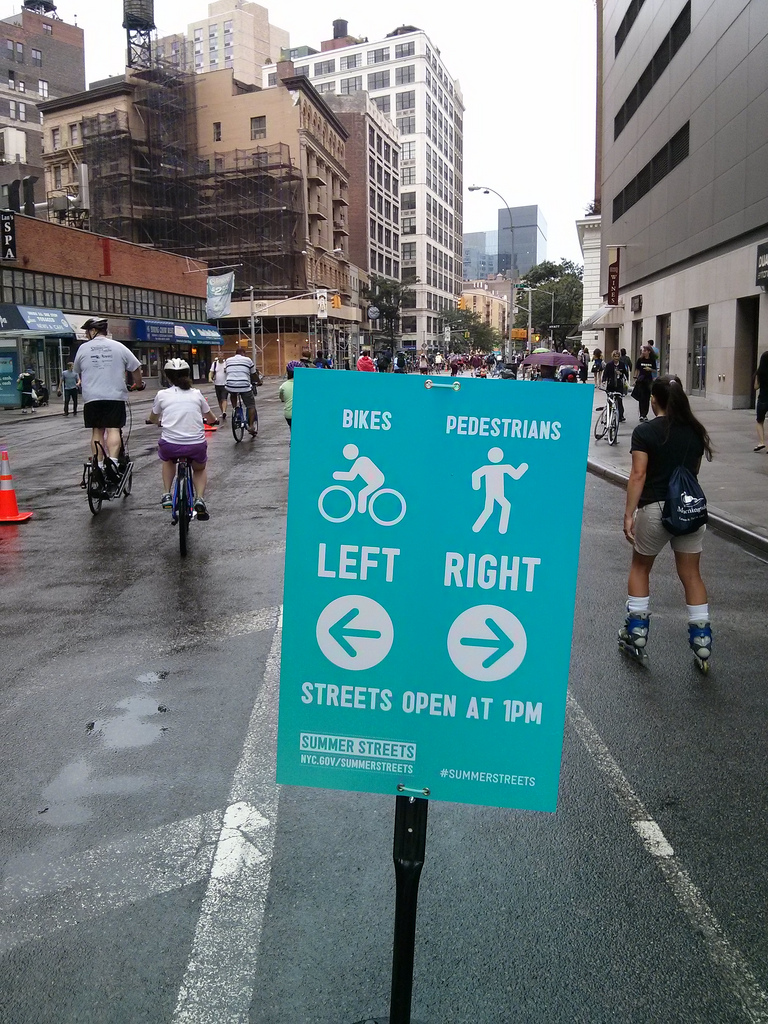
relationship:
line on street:
[576, 681, 763, 1017] [3, 386, 748, 1015]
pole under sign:
[387, 790, 433, 1017] [283, 360, 598, 824]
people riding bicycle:
[52, 316, 265, 457] [141, 409, 225, 576]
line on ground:
[561, 681, 761, 1017] [2, 379, 761, 1010]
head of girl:
[648, 373, 685, 416] [617, 368, 721, 676]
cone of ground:
[2, 446, 29, 518] [2, 379, 761, 1010]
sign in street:
[270, 365, 605, 845] [3, 386, 748, 1015]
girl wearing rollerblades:
[606, 332, 736, 699] [612, 598, 719, 680]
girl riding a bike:
[147, 309, 222, 545] [165, 455, 216, 565]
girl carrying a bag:
[606, 332, 736, 699] [654, 462, 708, 545]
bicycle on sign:
[309, 464, 417, 535] [283, 360, 598, 824]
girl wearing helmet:
[147, 309, 222, 545] [158, 360, 192, 390]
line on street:
[154, 587, 295, 1021] [3, 386, 748, 1015]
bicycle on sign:
[315, 477, 415, 541] [270, 365, 605, 845]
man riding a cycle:
[70, 318, 144, 482] [73, 450, 142, 532]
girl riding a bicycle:
[147, 351, 223, 524] [148, 449, 219, 567]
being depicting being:
[311, 429, 412, 535] [328, 438, 389, 516]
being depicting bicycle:
[311, 429, 412, 535] [309, 464, 417, 535]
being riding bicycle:
[328, 438, 389, 516] [309, 464, 417, 535]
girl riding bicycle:
[147, 309, 222, 545] [141, 409, 225, 576]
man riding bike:
[53, 287, 151, 539] [78, 375, 135, 518]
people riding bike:
[212, 317, 272, 476] [229, 371, 262, 446]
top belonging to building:
[261, 13, 424, 63] [260, 16, 469, 372]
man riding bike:
[53, 287, 151, 539] [80, 442, 138, 516]